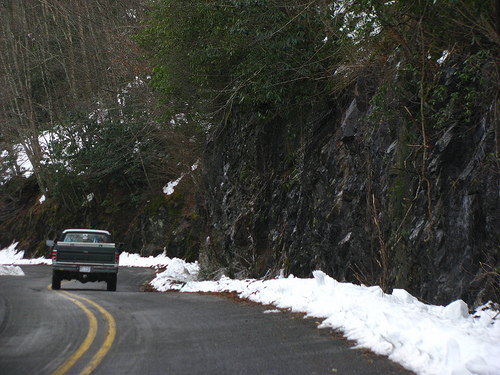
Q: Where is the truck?
A: On the road.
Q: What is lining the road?
A: Trees.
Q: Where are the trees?
A: On the side of the road.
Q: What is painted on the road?
A: A yellow stripe.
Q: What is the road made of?
A: Asphalt.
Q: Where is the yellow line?
A: Painted on the road.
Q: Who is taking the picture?
A: A photographer.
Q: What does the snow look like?
A: The snow is white.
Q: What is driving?
A: A black truck.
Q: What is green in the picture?
A: The leave.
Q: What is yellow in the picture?
A: The lines on the street.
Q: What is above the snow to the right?
A: A rock wall.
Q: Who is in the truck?
A: The driver.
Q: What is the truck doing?
A: Driving down the street.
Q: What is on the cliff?
A: Trees.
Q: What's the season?
A: Winter.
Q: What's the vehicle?
A: Truck.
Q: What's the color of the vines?
A: Green.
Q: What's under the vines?
A: Rock wall.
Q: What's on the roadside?
A: Snow.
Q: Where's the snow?
A: Roadside.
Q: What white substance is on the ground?
A: Snow.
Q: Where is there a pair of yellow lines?
A: Center of road.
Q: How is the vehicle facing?
A: Away.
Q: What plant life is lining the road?
A: Trees.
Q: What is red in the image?
A: Taillights.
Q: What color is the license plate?
A: White.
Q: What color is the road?
A: Black.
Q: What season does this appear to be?
A: Winter.